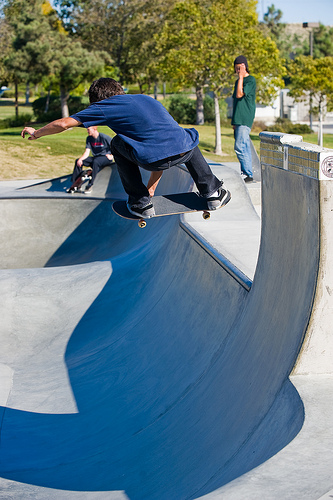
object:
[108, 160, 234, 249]
skater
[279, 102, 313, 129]
trash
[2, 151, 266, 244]
walkway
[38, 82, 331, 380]
park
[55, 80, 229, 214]
kids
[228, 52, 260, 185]
boy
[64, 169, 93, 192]
skateboard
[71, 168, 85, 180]
foot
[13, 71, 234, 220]
boy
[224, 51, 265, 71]
hat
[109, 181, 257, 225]
skateboard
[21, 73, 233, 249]
skateboarder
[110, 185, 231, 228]
skateboard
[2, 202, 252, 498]
shadow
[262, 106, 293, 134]
ground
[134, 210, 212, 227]
wheels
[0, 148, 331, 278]
skate rink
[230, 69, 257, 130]
shirt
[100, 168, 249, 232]
skateboard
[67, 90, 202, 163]
shirt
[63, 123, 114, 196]
boy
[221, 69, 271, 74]
his eye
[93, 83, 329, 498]
walls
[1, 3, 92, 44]
park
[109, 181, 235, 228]
skateboard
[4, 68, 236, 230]
guy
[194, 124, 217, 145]
ground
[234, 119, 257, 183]
jeans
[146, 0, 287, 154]
tree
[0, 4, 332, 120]
trees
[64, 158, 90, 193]
skateboard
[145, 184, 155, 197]
hand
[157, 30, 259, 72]
leaves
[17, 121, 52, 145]
hand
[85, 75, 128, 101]
hair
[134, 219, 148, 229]
wheel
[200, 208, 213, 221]
wheel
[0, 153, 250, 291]
rink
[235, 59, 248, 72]
face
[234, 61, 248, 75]
hand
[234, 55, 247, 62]
beanie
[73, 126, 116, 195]
man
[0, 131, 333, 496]
ramp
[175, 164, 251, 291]
edge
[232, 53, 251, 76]
head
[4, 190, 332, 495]
skateboard ramp